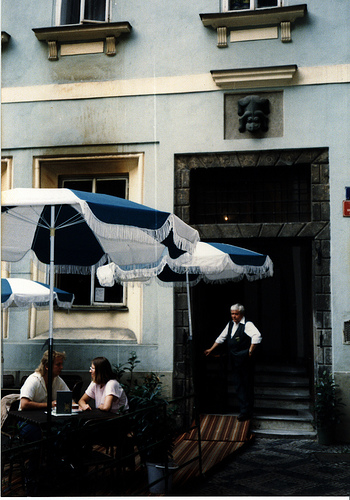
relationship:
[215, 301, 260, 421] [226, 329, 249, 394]
man wearing uniform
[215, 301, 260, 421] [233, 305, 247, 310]
man with hair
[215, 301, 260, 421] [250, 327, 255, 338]
man wearing shirt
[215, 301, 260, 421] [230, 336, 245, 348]
man wearing vest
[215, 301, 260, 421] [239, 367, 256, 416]
man wearing pants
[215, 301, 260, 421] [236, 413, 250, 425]
man wearing shoe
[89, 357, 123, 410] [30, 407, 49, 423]
person seated at table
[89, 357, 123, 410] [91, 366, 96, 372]
person wearing glasses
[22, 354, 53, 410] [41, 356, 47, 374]
man with hair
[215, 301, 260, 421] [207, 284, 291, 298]
man standing in doorway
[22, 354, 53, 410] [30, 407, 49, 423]
man seated at table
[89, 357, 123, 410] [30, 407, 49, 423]
person sitting at table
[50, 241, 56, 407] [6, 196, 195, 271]
pole supporting umbrella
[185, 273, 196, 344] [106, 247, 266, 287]
pole supporting umbrella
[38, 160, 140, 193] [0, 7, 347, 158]
window inside of building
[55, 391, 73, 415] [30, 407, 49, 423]
menu on top of table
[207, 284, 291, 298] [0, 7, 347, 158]
doorway of building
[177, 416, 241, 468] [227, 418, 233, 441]
rug has stripe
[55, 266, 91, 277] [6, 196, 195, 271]
fringe hanging on umbrella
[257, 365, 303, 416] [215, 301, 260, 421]
stairway behind man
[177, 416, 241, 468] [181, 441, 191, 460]
rug has stripe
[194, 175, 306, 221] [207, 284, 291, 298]
window over doorway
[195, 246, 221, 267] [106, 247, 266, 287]
panel sewn on umbrella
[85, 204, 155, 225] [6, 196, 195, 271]
panel sewn on umbrella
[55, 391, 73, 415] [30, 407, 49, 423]
menu standing on table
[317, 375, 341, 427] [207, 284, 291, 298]
plant next to doorway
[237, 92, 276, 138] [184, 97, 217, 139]
statue mounted on wall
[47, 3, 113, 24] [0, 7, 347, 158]
window of building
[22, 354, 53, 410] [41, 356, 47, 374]
man has hair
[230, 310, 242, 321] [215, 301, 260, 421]
head of man